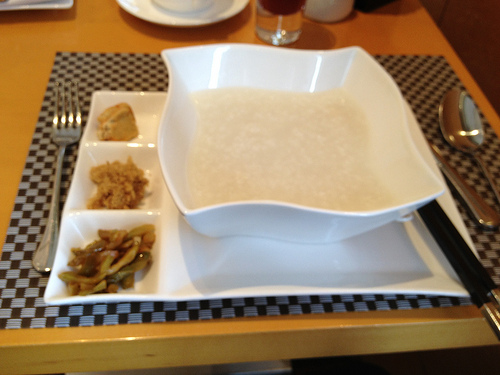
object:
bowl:
[155, 42, 449, 242]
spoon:
[437, 86, 499, 205]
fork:
[31, 81, 82, 273]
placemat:
[0, 50, 499, 332]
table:
[0, 1, 499, 373]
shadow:
[300, 21, 336, 50]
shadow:
[176, 213, 433, 298]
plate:
[40, 88, 477, 307]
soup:
[189, 86, 398, 212]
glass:
[254, 0, 302, 45]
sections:
[51, 91, 165, 301]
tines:
[49, 80, 81, 131]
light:
[456, 126, 480, 139]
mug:
[150, 0, 214, 14]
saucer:
[113, 0, 252, 28]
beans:
[58, 223, 157, 296]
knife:
[428, 131, 498, 230]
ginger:
[86, 157, 151, 210]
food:
[92, 102, 139, 142]